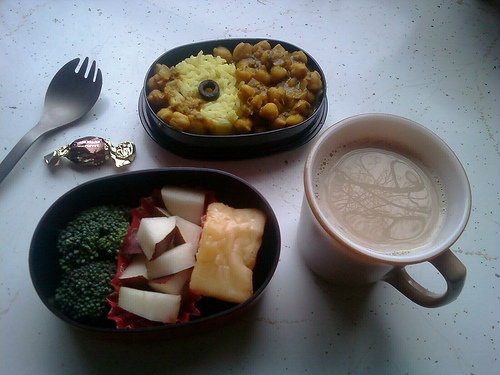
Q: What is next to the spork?
A: Candy.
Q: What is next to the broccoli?
A: Apples.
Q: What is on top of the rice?
A: Olive.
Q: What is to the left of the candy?
A: Spork.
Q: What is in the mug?
A: Latte.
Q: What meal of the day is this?
A: Lunch.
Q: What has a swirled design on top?
A: Latte.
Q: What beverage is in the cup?
A: Tea.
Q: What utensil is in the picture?
A: A spork.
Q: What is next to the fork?
A: A piece of candy.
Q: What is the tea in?
A: A white mug.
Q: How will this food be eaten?
A: With the spork.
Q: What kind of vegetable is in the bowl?
A: Broccoli.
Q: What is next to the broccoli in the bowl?
A: Apple.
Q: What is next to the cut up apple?
A: A wedge of cheese.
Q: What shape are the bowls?
A: Oval.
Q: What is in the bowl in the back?
A: Rice and beans.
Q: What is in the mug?
A: Coffee.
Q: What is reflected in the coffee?
A: Trees.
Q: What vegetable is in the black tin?
A: Broccoli.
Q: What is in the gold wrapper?
A: Candy.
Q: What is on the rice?
A: Olive.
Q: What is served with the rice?
A: Chick peas.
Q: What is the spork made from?
A: Black plastic.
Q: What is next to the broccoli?
A: Apples.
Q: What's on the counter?
A: Black dots.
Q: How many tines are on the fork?
A: Four.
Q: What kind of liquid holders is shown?
A: A mug.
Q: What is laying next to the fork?
A: Candy.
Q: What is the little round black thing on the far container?
A: An olive.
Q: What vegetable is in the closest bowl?
A: Broccoli.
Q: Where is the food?
A: On the table.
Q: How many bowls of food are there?
A: Two.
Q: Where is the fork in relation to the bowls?
A: To the left.